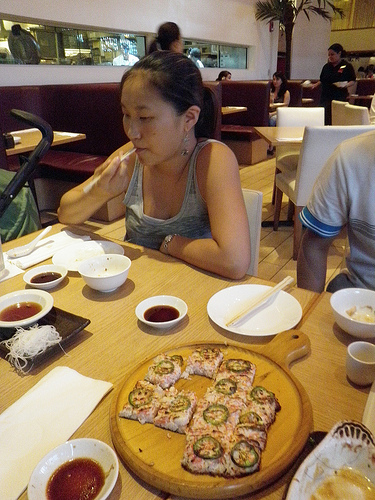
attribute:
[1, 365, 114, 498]
napkin — white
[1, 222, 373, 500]
table — joined, tan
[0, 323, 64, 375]
noodles — white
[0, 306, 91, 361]
plate — black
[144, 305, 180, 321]
sauce — soy, dark, brown, red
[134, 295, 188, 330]
bowl — small, white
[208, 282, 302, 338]
plate — empty, white, round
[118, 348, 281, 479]
pizza — sliced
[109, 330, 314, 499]
board — wood, round, wooden, flat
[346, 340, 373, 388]
cup — white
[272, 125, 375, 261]
chair — white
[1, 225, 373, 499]
food — asian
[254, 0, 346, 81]
tree — artificial, palm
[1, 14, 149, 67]
window — long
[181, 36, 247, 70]
window — long